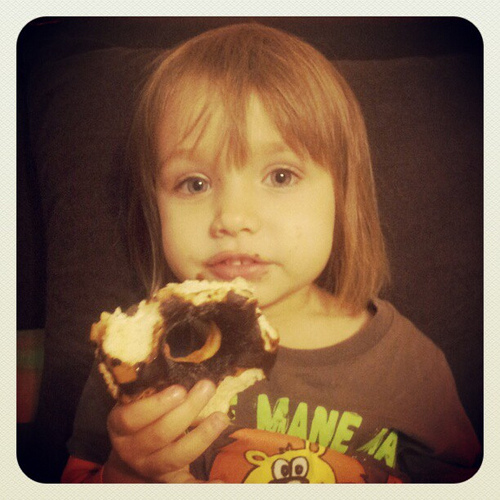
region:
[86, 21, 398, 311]
beautiful little girl with brown hair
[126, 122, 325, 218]
two big brown eyes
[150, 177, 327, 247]
cute little nose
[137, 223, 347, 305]
a cute mouth with crumbs on it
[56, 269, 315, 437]
big chocolate iced do nut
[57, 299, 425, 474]
little girl wearing a black pullover with a M on it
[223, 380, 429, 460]
little girl wearing a black pullover with a a on it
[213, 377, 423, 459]
little girl wearing a black pullover with a n on it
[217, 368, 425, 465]
little girl wearing a black pullover with a Me on it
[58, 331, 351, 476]
little girl holding a do nut with three fingers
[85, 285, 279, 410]
A slightly eaten donut in the girl's hand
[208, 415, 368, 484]
the lion on the tshirt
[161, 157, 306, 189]
the blue eyes of the girl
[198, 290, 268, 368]
some of the chocolate frosting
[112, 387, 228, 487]
the hand holding the donut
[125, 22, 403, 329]
the short hair on the girl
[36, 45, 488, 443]
the chair behind the girl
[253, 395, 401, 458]
the writing on the shirt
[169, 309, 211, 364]
the center of the donut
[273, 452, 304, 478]
the eyes of the lion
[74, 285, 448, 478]
A brown shirt with a lion pictured on front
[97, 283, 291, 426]
A half eaten chocolate covered donut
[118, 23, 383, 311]
A little child eating a donut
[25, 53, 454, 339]
A brown pillow behind a child's head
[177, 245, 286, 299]
Chocolate smeared on a little child's mouth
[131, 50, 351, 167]
Bangs on a little child's forehead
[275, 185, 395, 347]
Short hair brushing a shoulder top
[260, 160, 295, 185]
Light reflecting in an eye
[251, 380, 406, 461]
Yellow letters on a brown shirt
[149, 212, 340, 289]
Chubby cheeks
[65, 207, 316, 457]
The donut is covered in chocolate.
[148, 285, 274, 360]
The frosting is brown.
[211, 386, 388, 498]
The lion is orange and yellow.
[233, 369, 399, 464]
The text is green.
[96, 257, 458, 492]
The girls shirt is brown.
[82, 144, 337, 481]
The girl is eating a donut.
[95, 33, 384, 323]
The girl's hair is blonde.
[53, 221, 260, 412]
The donut has bites taken out of it.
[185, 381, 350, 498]
The animal is a lion.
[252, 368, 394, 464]
The shirt says Mane.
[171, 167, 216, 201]
the eye of a girl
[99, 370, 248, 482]
the hand of a girl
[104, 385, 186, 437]
the finger of a girl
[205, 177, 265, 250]
the nose of a girl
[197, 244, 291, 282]
the mouth of a girl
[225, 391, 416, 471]
green writing on the shirt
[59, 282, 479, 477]
a gray tee shirt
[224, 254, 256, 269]
the teeth of the girl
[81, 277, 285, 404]
a brown donut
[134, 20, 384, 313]
the head of the girl